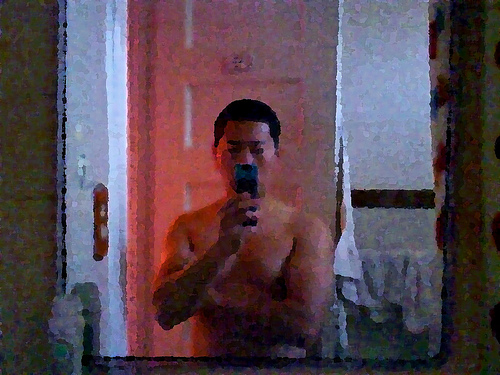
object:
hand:
[216, 193, 261, 256]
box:
[94, 183, 110, 260]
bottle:
[47, 294, 86, 367]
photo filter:
[7, 7, 488, 367]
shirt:
[331, 131, 363, 280]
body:
[151, 195, 334, 358]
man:
[152, 99, 334, 366]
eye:
[228, 146, 240, 154]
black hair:
[213, 98, 281, 149]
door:
[124, 0, 334, 354]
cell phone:
[229, 163, 261, 226]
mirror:
[59, 0, 453, 373]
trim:
[351, 189, 434, 208]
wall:
[340, 2, 445, 361]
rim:
[440, 222, 456, 367]